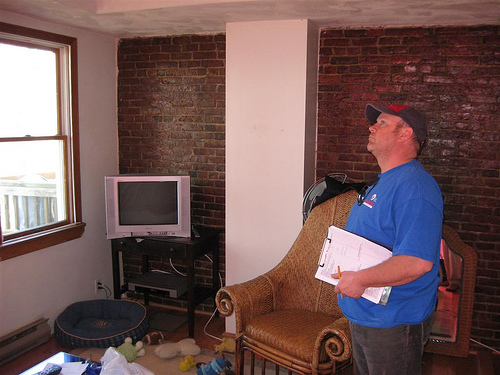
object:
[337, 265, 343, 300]
pencil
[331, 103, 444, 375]
man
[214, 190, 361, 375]
chair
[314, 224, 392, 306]
clipboard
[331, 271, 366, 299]
hand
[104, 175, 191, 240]
television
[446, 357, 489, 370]
ground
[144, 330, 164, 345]
toys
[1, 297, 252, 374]
floor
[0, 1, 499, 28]
ceiling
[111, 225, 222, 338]
stand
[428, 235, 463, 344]
mirror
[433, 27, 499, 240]
wall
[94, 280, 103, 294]
electrical outlet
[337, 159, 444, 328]
shirt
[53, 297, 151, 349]
bed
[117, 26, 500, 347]
wall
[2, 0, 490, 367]
room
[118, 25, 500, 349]
brick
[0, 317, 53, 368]
heater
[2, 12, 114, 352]
wall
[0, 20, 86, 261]
window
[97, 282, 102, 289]
plug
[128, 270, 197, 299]
unit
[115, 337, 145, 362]
toy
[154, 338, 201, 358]
toy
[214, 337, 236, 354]
toy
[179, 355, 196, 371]
toy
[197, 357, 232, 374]
toy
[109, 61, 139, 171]
corner